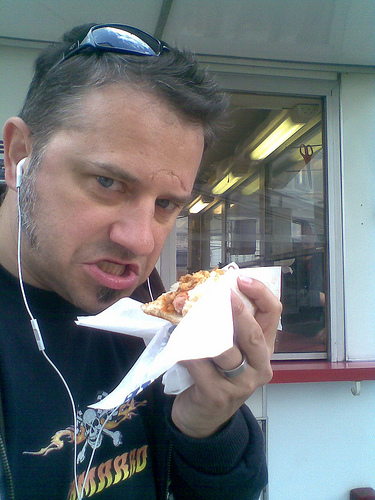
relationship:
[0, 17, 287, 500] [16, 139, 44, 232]
man has burn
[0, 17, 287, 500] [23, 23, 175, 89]
man has glasses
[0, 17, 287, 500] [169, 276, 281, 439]
man wearing ring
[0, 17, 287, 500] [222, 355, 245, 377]
man wearing ring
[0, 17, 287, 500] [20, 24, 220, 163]
man with hair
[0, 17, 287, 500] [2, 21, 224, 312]
man has head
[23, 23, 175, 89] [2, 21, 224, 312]
glasses on head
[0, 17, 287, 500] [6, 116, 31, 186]
man has ear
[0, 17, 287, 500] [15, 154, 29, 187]
man with earbud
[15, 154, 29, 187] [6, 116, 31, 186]
earbud in ear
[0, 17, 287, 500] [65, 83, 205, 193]
man with forehead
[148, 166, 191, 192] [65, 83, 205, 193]
scar on forehead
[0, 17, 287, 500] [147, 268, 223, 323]
man displeased with hot dog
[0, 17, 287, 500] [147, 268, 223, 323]
man with hot dog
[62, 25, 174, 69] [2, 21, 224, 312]
glasses on head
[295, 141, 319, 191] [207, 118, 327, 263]
scissors hanging in window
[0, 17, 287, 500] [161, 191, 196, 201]
man has eyebrow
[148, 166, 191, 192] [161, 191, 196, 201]
scar on top of eyebrow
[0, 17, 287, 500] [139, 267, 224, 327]
man holding food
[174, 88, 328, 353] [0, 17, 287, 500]
window behind man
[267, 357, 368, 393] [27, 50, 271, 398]
counter behind man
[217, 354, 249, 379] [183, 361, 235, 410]
ring on finger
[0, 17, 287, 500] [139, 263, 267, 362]
man eats pizza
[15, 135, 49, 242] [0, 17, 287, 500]
burn of man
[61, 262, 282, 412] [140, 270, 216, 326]
napkin surrounds hot dog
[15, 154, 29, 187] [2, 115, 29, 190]
earbud in mans ear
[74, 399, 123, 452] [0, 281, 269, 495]
skull on black shirt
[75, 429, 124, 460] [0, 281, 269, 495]
crossbones on black shirt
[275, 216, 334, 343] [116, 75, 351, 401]
man at shop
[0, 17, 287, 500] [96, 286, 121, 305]
man with a beard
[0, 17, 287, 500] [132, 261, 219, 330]
man eating hot dog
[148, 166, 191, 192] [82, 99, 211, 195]
scar on forehead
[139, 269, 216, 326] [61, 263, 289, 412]
hot dog in napkin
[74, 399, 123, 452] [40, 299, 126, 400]
skull on shirt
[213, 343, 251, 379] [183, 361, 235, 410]
ring on finger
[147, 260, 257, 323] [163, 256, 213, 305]
pizza with meat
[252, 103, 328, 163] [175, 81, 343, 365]
light from window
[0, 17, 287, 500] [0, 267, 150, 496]
man wearing shirt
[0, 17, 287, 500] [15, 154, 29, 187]
man wearing earbud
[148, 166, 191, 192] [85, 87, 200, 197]
scar on forehead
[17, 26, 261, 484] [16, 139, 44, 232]
man has burn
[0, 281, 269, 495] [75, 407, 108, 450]
black shirt has skull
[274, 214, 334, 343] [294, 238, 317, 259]
man has expression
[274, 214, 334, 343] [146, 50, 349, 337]
man inside shop